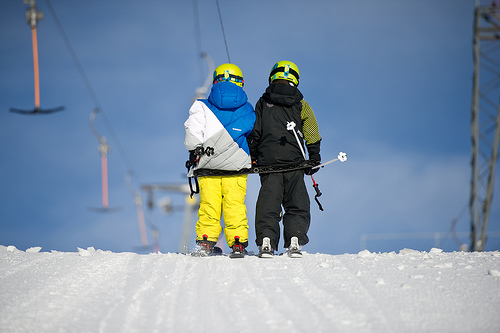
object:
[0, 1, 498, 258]
sky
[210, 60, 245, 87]
helmet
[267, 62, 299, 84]
helmet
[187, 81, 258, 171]
jacket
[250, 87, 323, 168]
jacket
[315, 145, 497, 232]
clouds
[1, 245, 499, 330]
snow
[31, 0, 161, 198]
wire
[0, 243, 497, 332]
ground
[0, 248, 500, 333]
ski slope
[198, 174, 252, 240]
snowpants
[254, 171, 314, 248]
pants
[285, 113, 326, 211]
poles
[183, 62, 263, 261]
skier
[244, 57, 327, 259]
skier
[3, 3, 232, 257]
ski lift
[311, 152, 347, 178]
pole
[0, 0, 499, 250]
distance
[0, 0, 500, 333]
air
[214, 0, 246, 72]
wire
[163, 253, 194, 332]
ski track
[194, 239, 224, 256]
boots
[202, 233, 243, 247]
trim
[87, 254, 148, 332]
track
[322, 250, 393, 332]
track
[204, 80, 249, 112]
hood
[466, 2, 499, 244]
post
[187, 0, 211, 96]
line